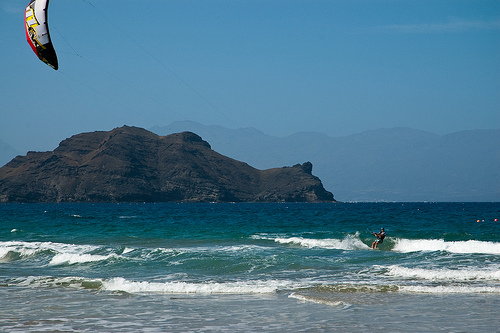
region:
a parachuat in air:
[18, 9, 63, 69]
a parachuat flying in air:
[19, 5, 79, 85]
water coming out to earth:
[91, 240, 205, 301]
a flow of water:
[303, 218, 467, 250]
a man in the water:
[355, 220, 415, 269]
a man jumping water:
[339, 227, 426, 277]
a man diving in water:
[340, 215, 415, 260]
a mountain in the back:
[32, 108, 320, 209]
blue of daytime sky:
[1, 2, 497, 132]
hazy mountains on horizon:
[155, 118, 497, 206]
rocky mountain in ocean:
[1, 125, 493, 236]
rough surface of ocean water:
[1, 202, 496, 247]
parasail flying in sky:
[23, 1, 60, 69]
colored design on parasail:
[22, 1, 58, 70]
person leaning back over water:
[368, 224, 388, 249]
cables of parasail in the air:
[55, 0, 375, 237]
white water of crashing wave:
[300, 237, 498, 257]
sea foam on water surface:
[3, 287, 480, 331]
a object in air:
[18, 10, 72, 72]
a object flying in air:
[6, 13, 80, 79]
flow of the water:
[134, 258, 268, 298]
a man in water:
[349, 195, 416, 280]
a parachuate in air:
[16, 15, 92, 81]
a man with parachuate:
[2, 4, 419, 291]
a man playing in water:
[328, 200, 410, 267]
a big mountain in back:
[28, 100, 405, 232]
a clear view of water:
[151, 187, 356, 232]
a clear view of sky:
[89, 5, 486, 140]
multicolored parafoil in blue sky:
[19, 1, 63, 73]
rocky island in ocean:
[1, 119, 346, 208]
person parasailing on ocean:
[363, 222, 390, 255]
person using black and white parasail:
[22, 4, 392, 257]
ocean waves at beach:
[5, 223, 361, 323]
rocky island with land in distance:
[0, 119, 499, 215]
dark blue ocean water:
[88, 201, 388, 224]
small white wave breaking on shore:
[98, 272, 393, 309]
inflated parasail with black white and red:
[18, 2, 66, 72]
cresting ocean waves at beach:
[11, 232, 128, 297]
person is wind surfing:
[22, 0, 384, 250]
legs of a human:
[371, 240, 378, 249]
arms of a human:
[372, 230, 383, 237]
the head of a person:
[380, 228, 385, 234]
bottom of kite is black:
[30, 42, 58, 69]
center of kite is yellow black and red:
[24, 0, 49, 47]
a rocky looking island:
[0, 125, 337, 200]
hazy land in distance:
[152, 120, 498, 200]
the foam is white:
[107, 278, 282, 293]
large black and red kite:
[21, 0, 58, 69]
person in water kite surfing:
[367, 223, 390, 248]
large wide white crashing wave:
[393, 236, 499, 254]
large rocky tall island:
[0, 121, 334, 202]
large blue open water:
[0, 199, 499, 331]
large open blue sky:
[0, 0, 499, 202]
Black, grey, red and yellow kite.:
[23, 1, 59, 71]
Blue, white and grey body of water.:
[3, 199, 499, 331]